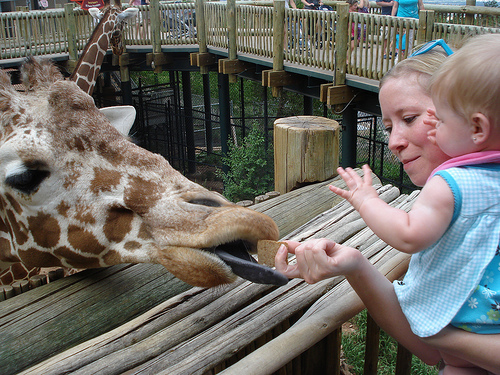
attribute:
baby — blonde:
[335, 36, 499, 330]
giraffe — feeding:
[1, 63, 287, 287]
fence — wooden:
[0, 3, 428, 91]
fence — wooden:
[0, 120, 419, 373]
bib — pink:
[432, 150, 500, 168]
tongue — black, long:
[216, 249, 287, 285]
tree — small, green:
[218, 127, 266, 197]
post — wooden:
[275, 113, 341, 189]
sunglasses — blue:
[408, 39, 452, 56]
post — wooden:
[338, 5, 350, 84]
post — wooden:
[272, 2, 285, 75]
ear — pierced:
[471, 115, 488, 144]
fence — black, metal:
[113, 86, 404, 186]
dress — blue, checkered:
[397, 169, 500, 337]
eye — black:
[9, 171, 49, 192]